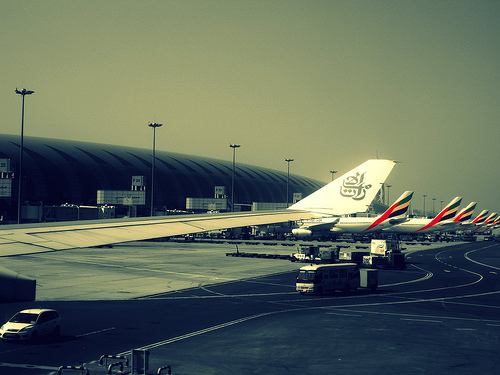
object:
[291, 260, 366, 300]
bus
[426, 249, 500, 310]
lines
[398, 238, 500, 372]
tarmac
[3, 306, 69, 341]
car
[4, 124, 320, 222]
airport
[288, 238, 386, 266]
luggage transporter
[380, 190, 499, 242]
tails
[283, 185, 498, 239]
planes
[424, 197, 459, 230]
stripe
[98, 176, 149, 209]
gate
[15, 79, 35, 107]
light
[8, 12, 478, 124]
sky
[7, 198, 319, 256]
wing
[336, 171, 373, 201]
logo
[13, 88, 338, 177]
lights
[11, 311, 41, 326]
windshield